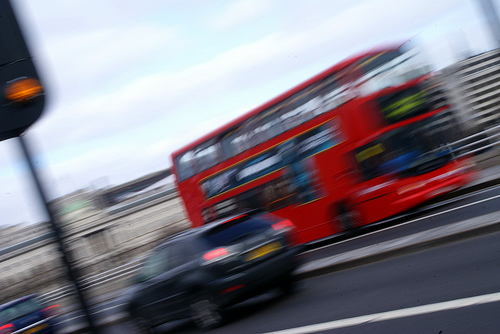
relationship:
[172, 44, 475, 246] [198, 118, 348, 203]
bus has a sign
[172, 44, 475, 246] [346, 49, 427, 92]
bus has a window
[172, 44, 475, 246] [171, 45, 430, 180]
bus has a top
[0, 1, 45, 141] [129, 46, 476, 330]
light for traffic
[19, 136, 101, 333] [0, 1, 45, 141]
pole has a light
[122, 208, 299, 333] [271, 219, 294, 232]
car has brake lights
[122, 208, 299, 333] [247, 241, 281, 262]
car has a license plate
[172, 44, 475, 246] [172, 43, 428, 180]
bus has a top level